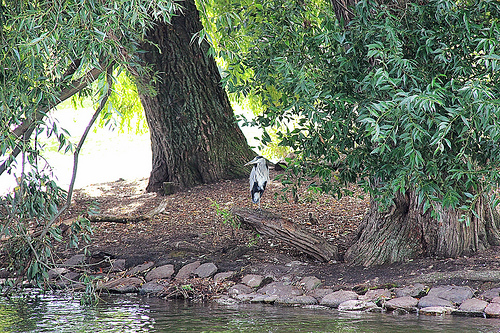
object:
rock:
[200, 265, 242, 287]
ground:
[0, 160, 500, 315]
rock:
[190, 261, 219, 279]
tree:
[327, 0, 500, 269]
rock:
[211, 270, 240, 283]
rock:
[299, 275, 322, 290]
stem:
[145, 164, 288, 197]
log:
[230, 207, 345, 267]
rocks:
[61, 252, 90, 267]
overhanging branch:
[1, 43, 123, 308]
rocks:
[42, 267, 70, 279]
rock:
[94, 277, 144, 294]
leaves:
[89, 29, 109, 37]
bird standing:
[242, 154, 270, 213]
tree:
[0, 0, 272, 313]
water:
[0, 283, 500, 332]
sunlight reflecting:
[28, 291, 155, 331]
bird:
[243, 154, 271, 219]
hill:
[0, 167, 376, 268]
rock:
[337, 299, 383, 314]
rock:
[425, 285, 479, 303]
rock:
[239, 273, 265, 288]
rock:
[140, 278, 173, 295]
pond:
[0, 282, 499, 332]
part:
[354, 122, 381, 154]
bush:
[185, 0, 500, 267]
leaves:
[397, 95, 418, 109]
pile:
[156, 276, 228, 302]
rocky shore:
[0, 244, 500, 320]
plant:
[201, 194, 263, 246]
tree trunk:
[124, 0, 276, 196]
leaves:
[219, 211, 227, 219]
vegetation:
[330, 34, 499, 198]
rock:
[320, 290, 359, 308]